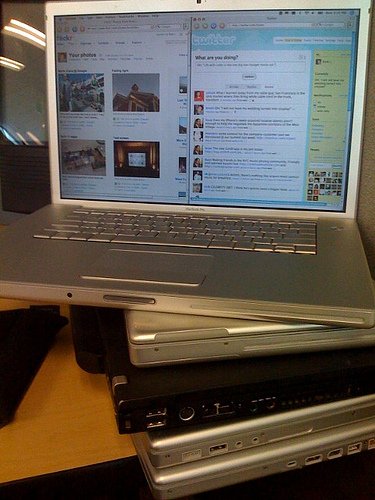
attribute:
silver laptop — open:
[0, 1, 373, 328]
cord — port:
[22, 298, 78, 376]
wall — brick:
[0, 144, 62, 219]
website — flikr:
[40, 11, 354, 206]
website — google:
[189, 12, 355, 209]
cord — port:
[353, 208, 372, 244]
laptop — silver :
[25, 31, 336, 266]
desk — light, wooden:
[0, 297, 138, 483]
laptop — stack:
[115, 285, 374, 369]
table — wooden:
[0, 303, 136, 489]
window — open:
[52, 5, 359, 215]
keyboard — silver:
[35, 202, 317, 260]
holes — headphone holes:
[236, 421, 273, 445]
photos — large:
[58, 66, 163, 183]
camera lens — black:
[195, 0, 201, 5]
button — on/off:
[328, 223, 343, 231]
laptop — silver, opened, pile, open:
[1, 1, 373, 327]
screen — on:
[58, 15, 351, 201]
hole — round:
[176, 405, 196, 419]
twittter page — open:
[186, 12, 353, 213]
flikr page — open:
[50, 6, 193, 207]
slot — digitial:
[302, 452, 324, 465]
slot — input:
[325, 444, 346, 461]